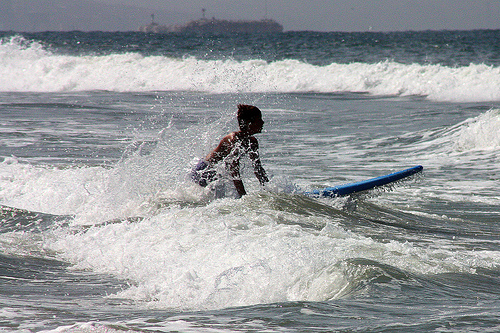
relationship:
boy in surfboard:
[187, 102, 271, 198] [274, 164, 424, 212]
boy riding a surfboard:
[187, 102, 271, 198] [332, 167, 379, 195]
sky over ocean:
[0, 1, 497, 33] [0, 29, 497, 332]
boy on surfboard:
[187, 102, 271, 198] [274, 164, 424, 212]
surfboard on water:
[274, 164, 424, 212] [1, 30, 498, 331]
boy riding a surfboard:
[187, 102, 271, 198] [101, 160, 427, 222]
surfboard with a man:
[274, 164, 424, 212] [177, 100, 272, 197]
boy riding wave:
[187, 105, 287, 202] [122, 198, 349, 298]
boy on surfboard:
[187, 105, 287, 202] [295, 159, 427, 224]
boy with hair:
[187, 102, 271, 198] [237, 103, 259, 124]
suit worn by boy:
[190, 160, 218, 191] [185, 102, 272, 199]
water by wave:
[1, 30, 498, 331] [6, 135, 402, 305]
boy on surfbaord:
[187, 102, 271, 198] [178, 155, 449, 224]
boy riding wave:
[187, 102, 271, 198] [71, 157, 371, 296]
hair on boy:
[234, 100, 257, 118] [185, 102, 272, 199]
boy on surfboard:
[187, 102, 271, 198] [267, 161, 429, 212]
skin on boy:
[213, 153, 216, 154] [188, 101, 255, 183]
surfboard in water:
[264, 160, 413, 213] [1, 206, 493, 327]